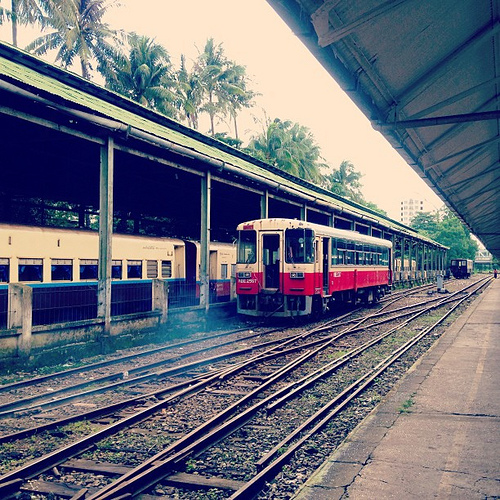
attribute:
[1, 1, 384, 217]
palm trees — in background, in a row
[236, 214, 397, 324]
trains — old, red, older, white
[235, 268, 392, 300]
pattern — red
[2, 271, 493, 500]
tracks — criss-crossing, several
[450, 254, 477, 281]
car — solitary, dark colored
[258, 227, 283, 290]
train door — wide open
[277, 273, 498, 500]
platform — cracked, made of concrete, paved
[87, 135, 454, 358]
support beams — made of steel, metal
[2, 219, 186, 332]
train — white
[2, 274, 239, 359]
fence — black, made of concrete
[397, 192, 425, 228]
building — white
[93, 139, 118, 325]
support beam — tall